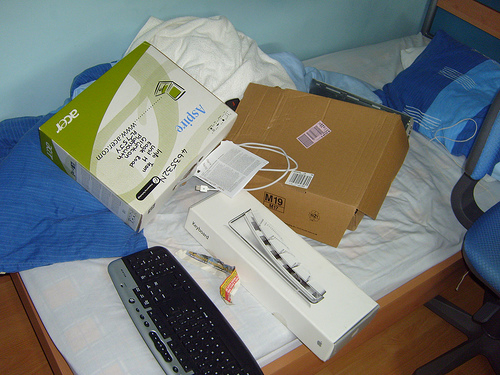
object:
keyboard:
[107, 244, 265, 373]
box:
[180, 183, 384, 364]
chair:
[406, 89, 498, 375]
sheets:
[15, 31, 468, 375]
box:
[219, 81, 413, 247]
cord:
[192, 140, 300, 194]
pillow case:
[370, 29, 500, 185]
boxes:
[35, 42, 241, 233]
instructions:
[191, 140, 270, 198]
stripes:
[415, 54, 499, 157]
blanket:
[123, 14, 299, 107]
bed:
[3, 29, 499, 374]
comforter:
[0, 50, 408, 276]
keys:
[138, 273, 148, 282]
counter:
[7, 268, 76, 374]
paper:
[175, 245, 241, 306]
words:
[173, 103, 207, 133]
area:
[37, 42, 149, 169]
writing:
[157, 146, 191, 186]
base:
[410, 292, 499, 375]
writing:
[51, 106, 84, 134]